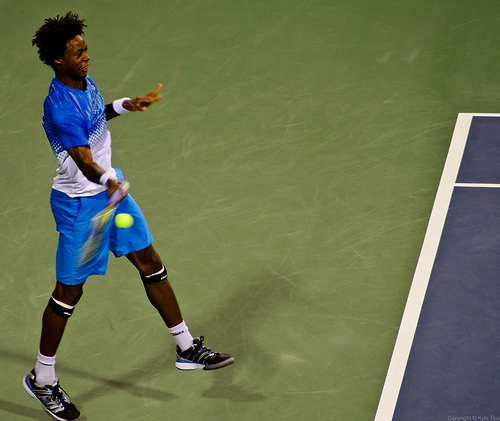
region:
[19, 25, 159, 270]
the man is holding a racket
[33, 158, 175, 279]
the short is blue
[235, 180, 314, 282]
the outer court is green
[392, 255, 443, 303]
the line is white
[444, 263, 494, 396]
inner court is blue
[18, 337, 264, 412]
the socks are white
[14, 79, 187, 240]
the shirt is blue and white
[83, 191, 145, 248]
the ball is yellow green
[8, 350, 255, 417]
the shoes are black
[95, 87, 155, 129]
the wrist band is white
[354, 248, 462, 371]
part of a tennis court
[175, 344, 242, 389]
left shoe of the player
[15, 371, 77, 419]
right shoe of the player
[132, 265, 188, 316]
left leg of the player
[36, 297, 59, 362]
right leg of the player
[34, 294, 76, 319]
black band on the right leg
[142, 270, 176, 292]
black band on the left leg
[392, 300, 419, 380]
white line in the court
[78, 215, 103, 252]
part of a racket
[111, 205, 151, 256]
a green tennis ball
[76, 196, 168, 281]
the man is heating the ball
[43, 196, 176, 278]
the man has a blue shirt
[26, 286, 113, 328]
the man has kneepads below his knee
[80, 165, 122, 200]
the wrist band is white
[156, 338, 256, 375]
his shoes are black and white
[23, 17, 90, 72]
his hair is unkempt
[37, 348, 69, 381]
hi socks are white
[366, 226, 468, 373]
the line is white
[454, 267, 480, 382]
the court is blue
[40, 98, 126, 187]
the shirt is blue and white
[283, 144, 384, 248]
part of a tennis court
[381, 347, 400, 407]
a white line on the court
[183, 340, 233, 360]
a shoe on the left leg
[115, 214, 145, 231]
a green tennis ball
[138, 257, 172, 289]
a black band on the left leg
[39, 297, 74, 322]
black band on the right leg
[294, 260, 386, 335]
green part of the court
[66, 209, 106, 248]
part of a racket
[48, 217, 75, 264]
part of a blue short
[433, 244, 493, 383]
purple part of the court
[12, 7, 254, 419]
Tennis player kicking a tennis ball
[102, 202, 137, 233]
Ball is green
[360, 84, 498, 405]
Tennis court is grey with white borders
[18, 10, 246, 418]
Tennis player wears blue and white shirt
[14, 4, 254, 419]
Player has blue short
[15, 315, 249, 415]
White socks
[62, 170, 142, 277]
Racket kicking the ball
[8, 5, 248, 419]
Racket on right hand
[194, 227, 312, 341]
Shadow of tennis player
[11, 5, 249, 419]
Tennis player has left leg up